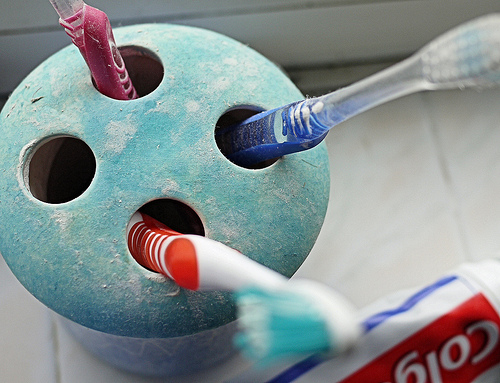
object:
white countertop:
[349, 180, 468, 260]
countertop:
[292, 89, 499, 306]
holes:
[20, 133, 97, 205]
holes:
[213, 103, 279, 170]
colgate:
[260, 260, 500, 383]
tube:
[261, 258, 499, 383]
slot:
[125, 198, 205, 277]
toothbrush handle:
[48, 0, 140, 100]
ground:
[0, 0, 500, 383]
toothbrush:
[49, 0, 138, 100]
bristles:
[232, 284, 330, 369]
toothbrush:
[126, 210, 358, 366]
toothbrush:
[222, 11, 500, 162]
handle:
[220, 94, 332, 165]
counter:
[0, 0, 500, 381]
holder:
[0, 23, 331, 377]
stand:
[0, 22, 329, 377]